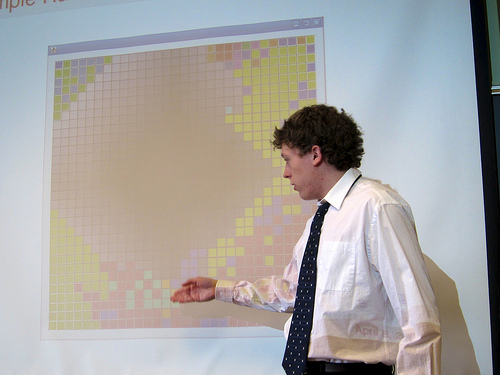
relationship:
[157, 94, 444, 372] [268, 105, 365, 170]
man with hair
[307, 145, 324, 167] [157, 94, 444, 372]
ear of man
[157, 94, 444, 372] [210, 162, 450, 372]
man wearing shirt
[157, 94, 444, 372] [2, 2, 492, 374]
man near white board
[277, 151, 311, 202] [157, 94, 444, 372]
face of man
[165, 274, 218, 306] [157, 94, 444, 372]
hand of a man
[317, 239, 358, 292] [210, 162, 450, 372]
pocket of shirt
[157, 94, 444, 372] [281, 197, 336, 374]
man wearing tie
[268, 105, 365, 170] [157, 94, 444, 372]
hair of man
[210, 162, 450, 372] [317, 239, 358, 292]
shirt has pocket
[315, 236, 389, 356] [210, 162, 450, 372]
words on shirt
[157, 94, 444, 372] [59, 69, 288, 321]
man front picture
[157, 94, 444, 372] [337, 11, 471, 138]
man front wall